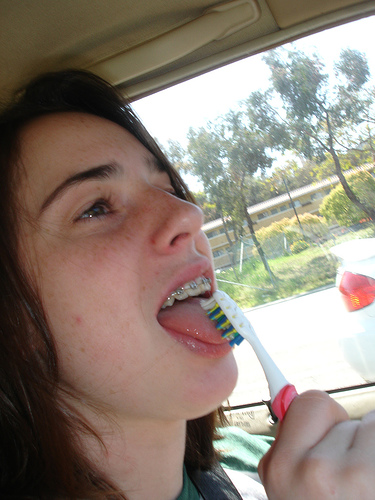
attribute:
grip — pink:
[263, 385, 302, 419]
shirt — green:
[175, 427, 276, 500]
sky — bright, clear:
[129, 21, 372, 183]